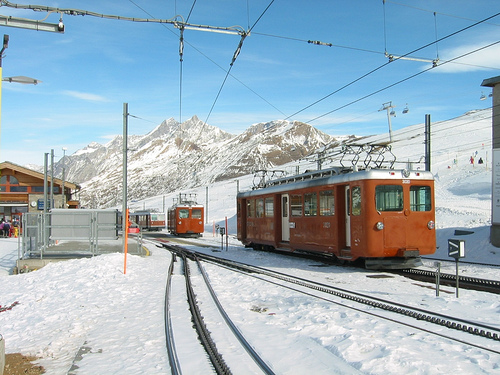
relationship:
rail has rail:
[153, 234, 500, 374] [153, 234, 500, 374]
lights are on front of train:
[368, 212, 448, 239] [232, 162, 456, 278]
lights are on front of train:
[172, 217, 204, 232] [165, 198, 204, 243]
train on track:
[232, 162, 456, 278] [167, 228, 499, 343]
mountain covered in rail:
[45, 110, 500, 253] [153, 234, 500, 374]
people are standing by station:
[4, 206, 17, 237] [4, 157, 81, 251]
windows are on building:
[0, 180, 58, 194] [2, 157, 81, 240]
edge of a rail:
[167, 346, 185, 374] [159, 243, 492, 375]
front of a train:
[335, 157, 447, 260] [232, 162, 456, 278]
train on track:
[165, 198, 204, 243] [167, 228, 499, 343]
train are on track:
[233, 162, 438, 272] [167, 228, 499, 343]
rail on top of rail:
[153, 234, 500, 374] [153, 234, 500, 374]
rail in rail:
[159, 243, 492, 375] [153, 234, 500, 374]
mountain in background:
[61, 110, 500, 253] [11, 5, 494, 234]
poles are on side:
[42, 138, 67, 261] [6, 17, 53, 375]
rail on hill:
[153, 234, 500, 374] [263, 126, 498, 269]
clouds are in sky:
[409, 30, 494, 98] [9, 2, 495, 164]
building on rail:
[0, 160, 82, 240] [153, 234, 500, 374]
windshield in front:
[370, 180, 439, 219] [335, 157, 447, 260]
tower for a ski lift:
[489, 71, 499, 251] [23, 2, 498, 74]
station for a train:
[4, 157, 81, 251] [232, 162, 456, 278]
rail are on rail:
[153, 234, 500, 374] [153, 234, 500, 374]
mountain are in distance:
[45, 110, 500, 253] [27, 71, 484, 202]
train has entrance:
[233, 162, 438, 272] [334, 177, 362, 262]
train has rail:
[232, 162, 456, 278] [153, 234, 500, 374]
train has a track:
[232, 162, 456, 278] [167, 228, 499, 343]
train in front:
[232, 162, 456, 278] [335, 157, 447, 260]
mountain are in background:
[45, 110, 500, 253] [11, 5, 494, 234]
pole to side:
[117, 102, 135, 282] [6, 17, 53, 375]